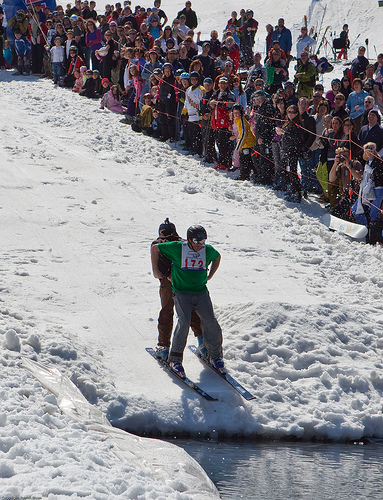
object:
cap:
[218, 76, 228, 84]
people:
[149, 217, 209, 360]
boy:
[233, 103, 257, 181]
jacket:
[233, 115, 257, 150]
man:
[150, 225, 222, 379]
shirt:
[158, 241, 221, 295]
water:
[140, 434, 383, 499]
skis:
[144, 346, 218, 403]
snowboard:
[321, 211, 368, 240]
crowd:
[0, 0, 383, 245]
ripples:
[223, 459, 366, 486]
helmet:
[190, 224, 213, 248]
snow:
[0, 103, 383, 498]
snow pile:
[214, 293, 373, 433]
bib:
[181, 241, 206, 270]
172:
[185, 258, 204, 269]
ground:
[0, 77, 383, 497]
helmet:
[187, 224, 207, 239]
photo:
[0, 0, 383, 499]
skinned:
[152, 259, 156, 270]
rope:
[111, 37, 383, 213]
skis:
[186, 342, 256, 401]